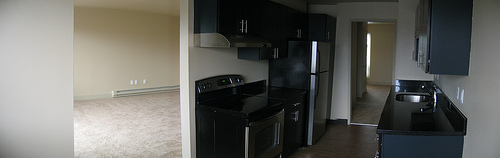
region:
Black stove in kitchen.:
[193, 74, 287, 156]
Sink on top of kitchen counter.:
[391, 85, 431, 106]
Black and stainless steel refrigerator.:
[288, 38, 333, 147]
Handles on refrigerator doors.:
[313, 47, 326, 108]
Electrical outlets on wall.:
[451, 85, 473, 106]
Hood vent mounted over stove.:
[234, 39, 291, 63]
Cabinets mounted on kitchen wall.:
[408, 2, 479, 78]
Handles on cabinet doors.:
[235, 16, 255, 36]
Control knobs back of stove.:
[198, 72, 248, 94]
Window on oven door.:
[247, 120, 289, 156]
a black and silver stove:
[196, 79, 291, 156]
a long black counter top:
[378, 70, 468, 141]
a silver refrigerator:
[303, 38, 330, 140]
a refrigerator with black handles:
[297, 44, 329, 120]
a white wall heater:
[99, 80, 177, 104]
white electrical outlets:
[117, 74, 151, 90]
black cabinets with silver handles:
[216, 16, 257, 40]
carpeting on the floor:
[105, 99, 161, 157]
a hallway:
[336, 23, 398, 132]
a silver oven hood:
[191, 32, 281, 56]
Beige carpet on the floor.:
[115, 97, 171, 152]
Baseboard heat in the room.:
[108, 78, 175, 103]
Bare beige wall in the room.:
[89, 20, 163, 67]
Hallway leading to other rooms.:
[343, 15, 400, 130]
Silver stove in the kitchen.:
[196, 58, 289, 156]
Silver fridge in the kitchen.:
[278, 29, 339, 149]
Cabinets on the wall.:
[228, 10, 339, 44]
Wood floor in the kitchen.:
[326, 133, 368, 152]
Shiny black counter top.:
[376, 80, 470, 146]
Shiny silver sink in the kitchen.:
[390, 79, 433, 110]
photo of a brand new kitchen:
[194, 9, 498, 146]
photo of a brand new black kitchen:
[222, 22, 487, 145]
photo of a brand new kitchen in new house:
[230, 33, 470, 142]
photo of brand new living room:
[78, 12, 176, 152]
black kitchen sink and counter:
[371, 62, 462, 149]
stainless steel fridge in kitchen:
[266, 30, 332, 150]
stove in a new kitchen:
[195, 65, 296, 151]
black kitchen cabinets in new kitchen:
[200, 2, 308, 49]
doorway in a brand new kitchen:
[355, 20, 398, 122]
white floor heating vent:
[109, 84, 188, 96]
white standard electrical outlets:
[126, 78, 149, 86]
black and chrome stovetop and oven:
[192, 72, 287, 157]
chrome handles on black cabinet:
[229, 14, 254, 36]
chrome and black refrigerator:
[263, 42, 335, 144]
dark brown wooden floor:
[282, 122, 377, 157]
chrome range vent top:
[193, 35, 276, 50]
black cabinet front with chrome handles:
[285, 88, 308, 155]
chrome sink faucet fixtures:
[412, 85, 443, 117]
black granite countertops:
[376, 75, 465, 137]